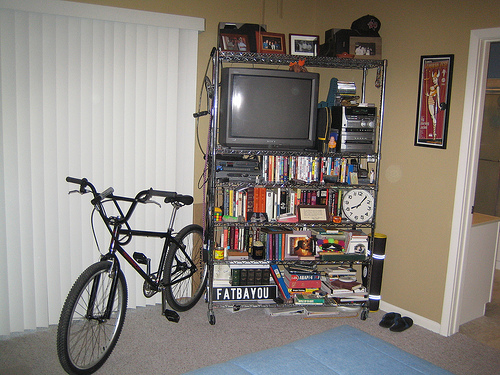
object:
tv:
[217, 66, 323, 150]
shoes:
[386, 316, 414, 334]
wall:
[373, 5, 463, 313]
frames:
[214, 49, 389, 69]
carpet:
[2, 325, 499, 374]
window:
[218, 189, 344, 257]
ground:
[417, 137, 442, 145]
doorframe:
[440, 28, 494, 339]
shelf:
[212, 149, 380, 160]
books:
[232, 268, 240, 286]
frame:
[402, 246, 468, 338]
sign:
[212, 286, 278, 301]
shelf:
[210, 301, 368, 309]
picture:
[255, 30, 285, 54]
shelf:
[213, 259, 370, 266]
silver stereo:
[330, 101, 378, 155]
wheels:
[161, 223, 214, 313]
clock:
[340, 187, 376, 225]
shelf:
[210, 222, 374, 229]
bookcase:
[203, 45, 387, 318]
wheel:
[55, 260, 130, 374]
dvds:
[262, 152, 268, 185]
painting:
[412, 53, 455, 149]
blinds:
[1, 1, 205, 333]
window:
[1, 7, 199, 337]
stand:
[203, 48, 388, 326]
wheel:
[358, 309, 370, 320]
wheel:
[206, 313, 217, 326]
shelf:
[217, 51, 383, 68]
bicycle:
[55, 176, 212, 373]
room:
[3, 1, 494, 372]